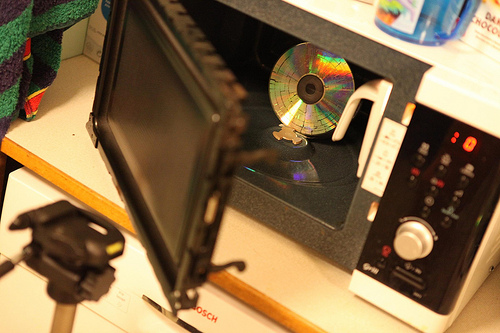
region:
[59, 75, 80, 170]
this is a table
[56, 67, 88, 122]
the table is white in color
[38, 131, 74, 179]
the table is wooden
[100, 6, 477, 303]
this is a microwave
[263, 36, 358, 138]
this is a cd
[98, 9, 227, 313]
this is the door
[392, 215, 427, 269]
this is a button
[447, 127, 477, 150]
this is a digit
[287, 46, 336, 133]
the cd is shiny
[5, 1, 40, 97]
this is a cloth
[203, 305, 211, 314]
word bosch is written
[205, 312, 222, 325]
word bosch is written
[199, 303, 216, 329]
word bosch is written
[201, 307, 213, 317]
word bosch is written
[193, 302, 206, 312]
word bosch is written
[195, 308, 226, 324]
word bosch is written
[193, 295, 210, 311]
word bosch is written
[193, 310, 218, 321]
word bosch is written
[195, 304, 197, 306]
word bosch is written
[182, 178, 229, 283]
edge of a microwave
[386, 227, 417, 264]
part of a switch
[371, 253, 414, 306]
part of a microwave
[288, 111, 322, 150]
part of a disc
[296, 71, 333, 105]
part of a space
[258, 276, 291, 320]
part of an edge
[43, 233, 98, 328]
part of a socket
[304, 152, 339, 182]
part of a surface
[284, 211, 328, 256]
edge of a microwave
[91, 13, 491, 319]
open door on microwave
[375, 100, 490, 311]
white knob on black panel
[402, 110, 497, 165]
punctuation and digit on top of panel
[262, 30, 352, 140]
rainbow of colors reflected off disk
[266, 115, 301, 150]
center piece of microwave turntable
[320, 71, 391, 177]
handle of white container inside microwave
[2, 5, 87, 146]
striped terry cloth on side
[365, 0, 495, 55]
blue container and package on top of appliance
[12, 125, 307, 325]
wood edge on shelf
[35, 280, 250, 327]
part of company name on appliance under shelf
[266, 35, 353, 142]
a cracked cd in a microwave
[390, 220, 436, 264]
a silver knob on a microwave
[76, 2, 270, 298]
an open black mirowave door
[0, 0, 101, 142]
a green navy and red striped towel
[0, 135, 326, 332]
a yellow edge on a white table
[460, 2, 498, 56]
a package of dark chocolate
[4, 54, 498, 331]
a white table under a microwave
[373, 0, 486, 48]
a blue cup on top of a microwave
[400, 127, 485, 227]
push buttons on a microwave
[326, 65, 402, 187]
a white handle inside a microwave